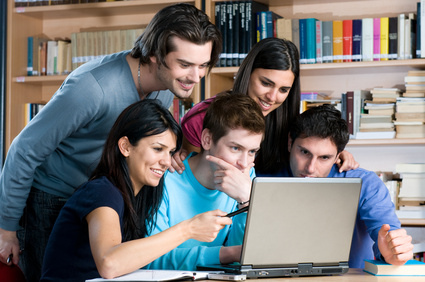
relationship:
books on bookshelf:
[16, 2, 424, 261] [2, 0, 191, 137]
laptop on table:
[196, 175, 361, 277] [169, 268, 424, 280]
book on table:
[85, 266, 213, 279] [191, 268, 423, 279]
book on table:
[364, 256, 424, 276] [191, 268, 423, 279]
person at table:
[285, 102, 417, 267] [191, 268, 423, 279]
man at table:
[142, 91, 267, 272] [191, 268, 423, 279]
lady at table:
[38, 98, 233, 282] [191, 268, 423, 279]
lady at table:
[168, 35, 359, 175] [191, 268, 423, 279]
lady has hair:
[38, 98, 233, 282] [88, 96, 183, 235]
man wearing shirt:
[0, 3, 224, 280] [0, 49, 175, 230]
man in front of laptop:
[139, 91, 265, 268] [196, 175, 361, 277]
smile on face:
[149, 166, 165, 175] [130, 126, 177, 186]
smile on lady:
[149, 166, 165, 175] [38, 98, 233, 282]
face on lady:
[130, 126, 177, 186] [38, 98, 233, 282]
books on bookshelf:
[16, 2, 424, 261] [4, 0, 424, 262]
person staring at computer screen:
[273, 102, 415, 267] [239, 176, 362, 268]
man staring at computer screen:
[142, 91, 267, 272] [239, 176, 362, 268]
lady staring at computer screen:
[38, 98, 233, 282] [239, 176, 362, 268]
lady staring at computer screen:
[168, 35, 359, 175] [239, 176, 362, 268]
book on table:
[364, 259, 424, 276] [169, 268, 424, 280]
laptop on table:
[196, 175, 361, 277] [176, 266, 424, 279]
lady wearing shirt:
[52, 98, 232, 280] [47, 175, 147, 279]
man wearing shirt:
[139, 91, 265, 268] [141, 149, 256, 268]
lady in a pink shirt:
[235, 35, 303, 122] [182, 95, 209, 146]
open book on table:
[81, 265, 216, 279] [107, 259, 412, 279]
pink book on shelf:
[371, 18, 381, 62] [213, 3, 412, 169]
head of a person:
[287, 104, 350, 178] [285, 102, 417, 267]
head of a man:
[200, 92, 264, 175] [142, 91, 267, 272]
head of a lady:
[104, 97, 181, 192] [38, 98, 233, 282]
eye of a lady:
[148, 139, 165, 154] [38, 98, 233, 282]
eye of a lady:
[152, 145, 165, 152] [38, 98, 233, 282]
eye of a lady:
[154, 144, 165, 152] [38, 98, 233, 282]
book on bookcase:
[388, 16, 398, 60] [201, 1, 425, 228]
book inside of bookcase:
[384, 8, 402, 58] [203, 3, 424, 240]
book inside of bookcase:
[338, 91, 362, 142] [199, 3, 423, 216]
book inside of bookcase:
[326, 17, 344, 62] [205, 5, 420, 262]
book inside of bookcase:
[342, 20, 351, 59] [205, 5, 420, 262]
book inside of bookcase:
[349, 20, 360, 63] [201, 1, 425, 228]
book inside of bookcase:
[359, 10, 379, 66] [201, 1, 425, 228]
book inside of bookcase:
[379, 10, 395, 60] [201, 1, 425, 228]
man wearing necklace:
[115, 12, 209, 107] [131, 56, 150, 97]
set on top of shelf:
[214, 7, 263, 61] [203, 3, 417, 72]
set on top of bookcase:
[57, 26, 152, 63] [201, 1, 425, 228]